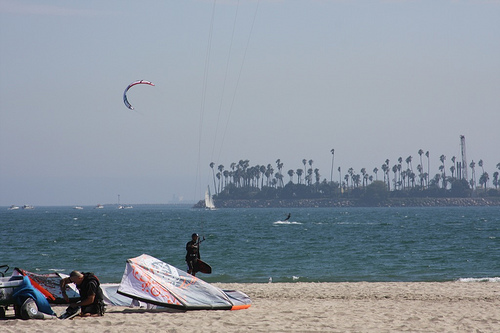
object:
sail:
[123, 80, 156, 110]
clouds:
[23, 47, 418, 151]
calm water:
[0, 205, 499, 283]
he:
[185, 233, 205, 279]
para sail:
[99, 253, 252, 309]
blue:
[273, 52, 376, 99]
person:
[284, 213, 291, 222]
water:
[6, 204, 498, 281]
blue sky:
[0, 0, 498, 207]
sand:
[0, 282, 499, 333]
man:
[60, 270, 108, 320]